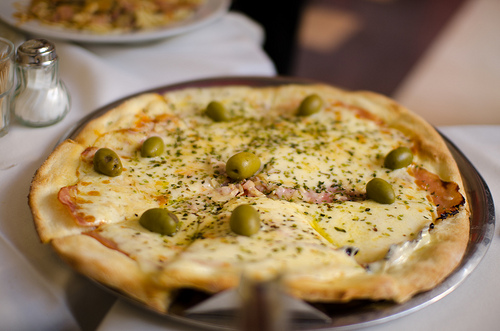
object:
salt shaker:
[2, 24, 71, 130]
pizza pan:
[28, 79, 499, 331]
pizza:
[101, 114, 432, 275]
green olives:
[209, 135, 282, 189]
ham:
[40, 185, 105, 229]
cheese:
[270, 129, 338, 186]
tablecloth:
[128, 48, 203, 75]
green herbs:
[268, 127, 342, 170]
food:
[29, 4, 213, 49]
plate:
[17, 27, 226, 44]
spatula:
[169, 276, 348, 331]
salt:
[15, 92, 69, 127]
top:
[10, 37, 58, 72]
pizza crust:
[326, 81, 435, 145]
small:
[400, 66, 492, 131]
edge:
[191, 58, 256, 89]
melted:
[320, 212, 401, 262]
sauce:
[346, 100, 387, 127]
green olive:
[90, 139, 127, 178]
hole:
[105, 150, 140, 181]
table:
[203, 19, 298, 71]